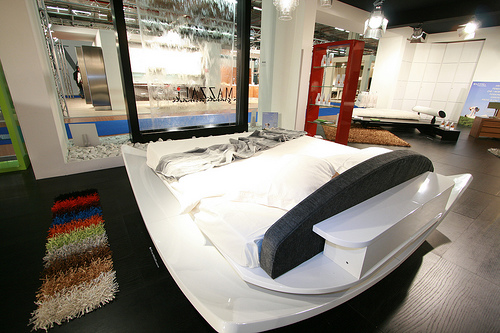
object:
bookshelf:
[303, 36, 364, 149]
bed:
[118, 129, 473, 332]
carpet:
[29, 185, 119, 332]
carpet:
[322, 118, 414, 149]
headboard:
[247, 151, 436, 281]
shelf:
[312, 170, 455, 278]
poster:
[457, 80, 499, 129]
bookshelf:
[0, 61, 33, 173]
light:
[359, 0, 391, 42]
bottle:
[319, 53, 326, 67]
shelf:
[311, 65, 350, 70]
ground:
[0, 122, 498, 332]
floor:
[0, 97, 358, 143]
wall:
[372, 23, 499, 136]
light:
[267, 0, 303, 21]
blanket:
[145, 121, 306, 179]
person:
[69, 63, 84, 102]